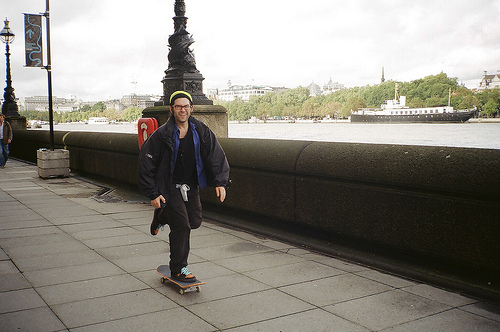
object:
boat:
[351, 81, 480, 124]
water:
[31, 123, 499, 151]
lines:
[23, 14, 43, 67]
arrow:
[25, 28, 34, 38]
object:
[137, 118, 159, 150]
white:
[139, 124, 150, 143]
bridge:
[8, 127, 500, 298]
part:
[297, 140, 499, 300]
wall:
[10, 132, 499, 299]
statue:
[160, 0, 206, 102]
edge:
[20, 127, 500, 154]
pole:
[44, 0, 58, 150]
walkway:
[0, 156, 499, 332]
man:
[137, 90, 231, 295]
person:
[0, 111, 13, 168]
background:
[0, 1, 500, 154]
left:
[1, 0, 145, 329]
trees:
[322, 101, 336, 117]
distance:
[0, 0, 500, 109]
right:
[309, 1, 499, 331]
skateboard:
[156, 264, 206, 296]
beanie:
[168, 89, 194, 103]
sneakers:
[150, 206, 197, 283]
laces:
[185, 272, 191, 275]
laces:
[161, 225, 165, 231]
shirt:
[169, 124, 208, 191]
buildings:
[21, 95, 73, 114]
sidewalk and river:
[0, 122, 499, 313]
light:
[0, 14, 27, 131]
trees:
[483, 86, 499, 115]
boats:
[312, 118, 321, 123]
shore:
[24, 110, 498, 123]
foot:
[170, 266, 196, 283]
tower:
[377, 62, 391, 89]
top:
[0, 7, 17, 57]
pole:
[0, 40, 25, 117]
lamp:
[166, 0, 196, 48]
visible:
[1, 0, 499, 331]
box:
[37, 148, 71, 179]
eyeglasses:
[172, 104, 192, 110]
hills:
[324, 71, 478, 116]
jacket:
[134, 115, 229, 201]